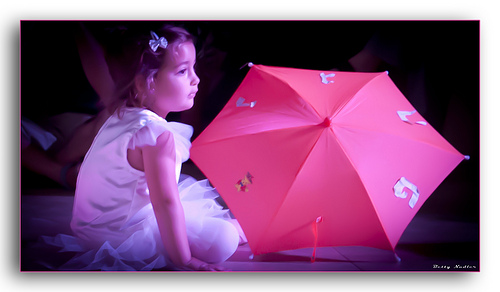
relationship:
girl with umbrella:
[77, 26, 202, 267] [192, 61, 464, 254]